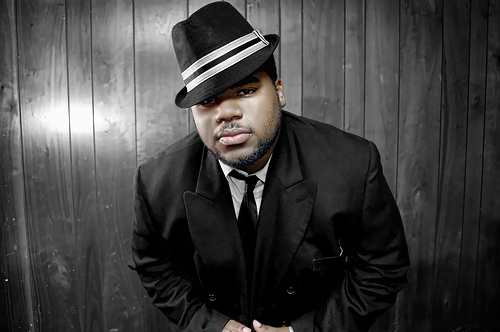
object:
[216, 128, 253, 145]
mouth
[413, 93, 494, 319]
wall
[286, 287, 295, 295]
button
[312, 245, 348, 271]
pocket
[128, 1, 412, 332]
man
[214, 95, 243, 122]
man's nose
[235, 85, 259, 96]
eye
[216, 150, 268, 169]
chin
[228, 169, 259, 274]
tie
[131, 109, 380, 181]
shoulder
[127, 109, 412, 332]
coat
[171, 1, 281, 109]
cap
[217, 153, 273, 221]
shirt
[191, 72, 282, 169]
face